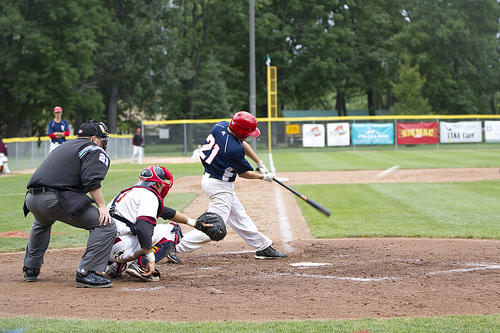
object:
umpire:
[22, 118, 115, 290]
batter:
[195, 101, 277, 259]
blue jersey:
[198, 127, 256, 182]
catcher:
[105, 160, 185, 286]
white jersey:
[107, 184, 164, 233]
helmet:
[227, 105, 263, 139]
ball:
[376, 163, 401, 179]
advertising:
[298, 117, 499, 149]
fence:
[15, 112, 499, 161]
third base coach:
[44, 105, 70, 145]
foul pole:
[264, 53, 279, 156]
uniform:
[24, 134, 111, 272]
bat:
[273, 176, 333, 220]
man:
[129, 127, 150, 165]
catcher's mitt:
[195, 209, 229, 243]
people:
[22, 101, 301, 283]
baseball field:
[0, 141, 498, 333]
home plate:
[290, 256, 331, 272]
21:
[200, 134, 222, 165]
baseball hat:
[51, 103, 66, 114]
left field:
[103, 142, 499, 172]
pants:
[191, 176, 270, 257]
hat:
[77, 119, 114, 136]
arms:
[48, 131, 74, 141]